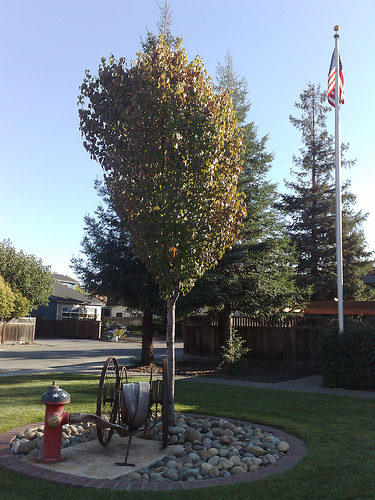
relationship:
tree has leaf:
[76, 32, 251, 429] [100, 56, 108, 64]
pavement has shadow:
[2, 338, 375, 400] [1, 346, 182, 361]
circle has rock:
[2, 408, 309, 493] [278, 442, 290, 454]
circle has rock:
[2, 408, 309, 493] [219, 433, 235, 447]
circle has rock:
[2, 408, 309, 493] [16, 439, 39, 453]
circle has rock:
[2, 408, 309, 493] [183, 424, 202, 445]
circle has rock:
[2, 408, 309, 493] [218, 447, 230, 457]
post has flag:
[333, 24, 345, 334] [326, 48, 347, 111]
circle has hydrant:
[2, 408, 309, 493] [35, 379, 71, 467]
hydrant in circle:
[35, 379, 71, 467] [2, 408, 309, 493]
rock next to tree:
[183, 424, 202, 445] [76, 32, 251, 429]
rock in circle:
[16, 439, 39, 453] [2, 408, 309, 493]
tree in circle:
[76, 32, 251, 429] [2, 408, 309, 493]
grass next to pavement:
[0, 370, 375, 498] [2, 338, 375, 400]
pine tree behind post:
[273, 80, 373, 301] [333, 24, 345, 334]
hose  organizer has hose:
[94, 356, 170, 451] [71, 382, 152, 437]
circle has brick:
[2, 408, 309, 493] [207, 476, 222, 489]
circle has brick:
[2, 408, 309, 493] [156, 482, 172, 492]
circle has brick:
[2, 408, 309, 493] [41, 468, 62, 480]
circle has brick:
[2, 408, 309, 493] [128, 480, 146, 492]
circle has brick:
[2, 408, 309, 493] [85, 475, 110, 490]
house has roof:
[34, 271, 105, 320] [49, 273, 104, 307]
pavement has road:
[2, 338, 375, 400] [0, 345, 186, 361]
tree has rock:
[76, 32, 251, 429] [183, 424, 202, 445]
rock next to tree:
[219, 433, 235, 447] [76, 32, 251, 429]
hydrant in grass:
[35, 379, 71, 467] [0, 370, 375, 498]